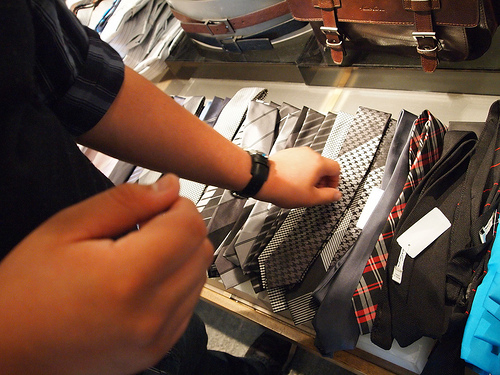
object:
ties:
[262, 104, 392, 293]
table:
[73, 84, 495, 370]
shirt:
[2, 0, 122, 235]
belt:
[169, 0, 295, 33]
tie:
[266, 106, 392, 292]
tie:
[352, 106, 448, 343]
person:
[4, 0, 345, 374]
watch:
[235, 149, 270, 204]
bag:
[291, 0, 498, 71]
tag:
[396, 201, 457, 261]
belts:
[315, 0, 351, 69]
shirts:
[66, 0, 188, 66]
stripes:
[350, 107, 444, 320]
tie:
[380, 129, 478, 348]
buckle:
[315, 23, 345, 48]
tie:
[307, 109, 420, 359]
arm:
[21, 0, 264, 199]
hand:
[2, 172, 227, 373]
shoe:
[243, 329, 302, 371]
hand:
[262, 136, 349, 213]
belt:
[186, 18, 310, 53]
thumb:
[47, 168, 185, 237]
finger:
[112, 199, 206, 288]